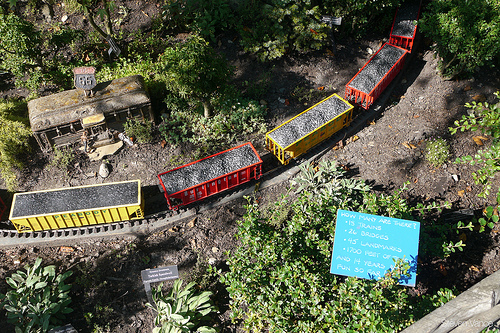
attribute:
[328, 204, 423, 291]
sign — blue, informational, large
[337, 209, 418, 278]
writing — white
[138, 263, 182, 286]
sign — black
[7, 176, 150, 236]
train car — yellow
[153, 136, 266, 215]
train car — red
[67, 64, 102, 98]
sign — rusty, little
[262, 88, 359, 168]
train car — yellow